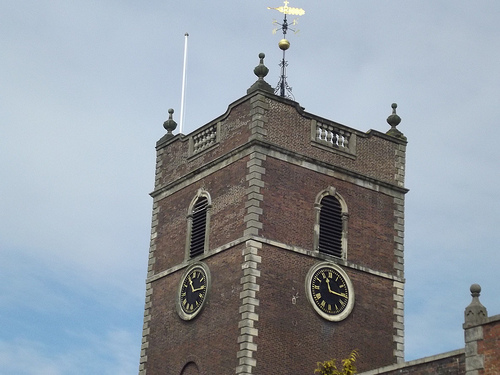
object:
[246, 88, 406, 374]
wall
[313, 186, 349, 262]
window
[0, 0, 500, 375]
sky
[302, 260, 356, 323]
clock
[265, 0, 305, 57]
tip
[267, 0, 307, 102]
vane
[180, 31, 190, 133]
rod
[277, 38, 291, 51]
ball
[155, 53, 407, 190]
top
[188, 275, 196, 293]
hand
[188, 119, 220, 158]
ledge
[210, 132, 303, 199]
color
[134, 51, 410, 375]
building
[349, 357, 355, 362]
leafs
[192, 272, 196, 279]
12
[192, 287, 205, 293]
hands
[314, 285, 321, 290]
numbers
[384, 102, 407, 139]
spire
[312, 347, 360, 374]
tree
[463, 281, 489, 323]
knob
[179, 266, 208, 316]
face